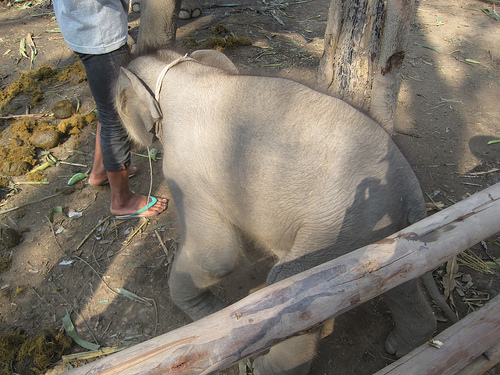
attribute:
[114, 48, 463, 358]
elephant — grey, here, small, present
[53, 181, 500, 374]
fence — wooden, large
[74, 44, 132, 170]
jeans — grey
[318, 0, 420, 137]
trunk — tan, medium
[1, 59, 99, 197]
poop — here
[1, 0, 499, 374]
ground — dirty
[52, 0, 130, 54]
shirt — blue, white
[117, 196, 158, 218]
flip flop — teal, blue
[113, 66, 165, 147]
ears — floppy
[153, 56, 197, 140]
string — here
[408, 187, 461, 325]
tail — here